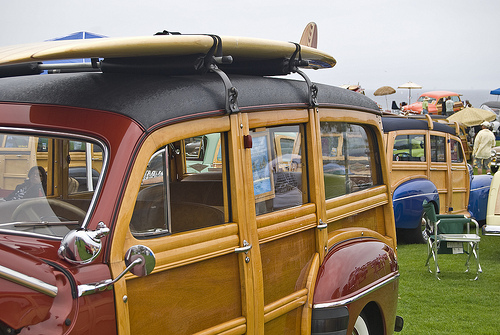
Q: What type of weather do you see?
A: It is overcast.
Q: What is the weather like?
A: It is overcast.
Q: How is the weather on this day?
A: It is overcast.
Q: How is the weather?
A: It is overcast.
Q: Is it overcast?
A: Yes, it is overcast.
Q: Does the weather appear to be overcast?
A: Yes, it is overcast.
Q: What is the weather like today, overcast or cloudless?
A: It is overcast.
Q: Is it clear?
A: No, it is overcast.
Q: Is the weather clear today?
A: No, it is overcast.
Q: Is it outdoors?
A: Yes, it is outdoors.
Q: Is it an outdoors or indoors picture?
A: It is outdoors.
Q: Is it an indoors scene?
A: No, it is outdoors.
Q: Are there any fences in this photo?
A: No, there are no fences.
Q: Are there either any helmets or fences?
A: No, there are no fences or helmets.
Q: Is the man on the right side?
A: Yes, the man is on the right of the image.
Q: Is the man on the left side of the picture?
A: No, the man is on the right of the image.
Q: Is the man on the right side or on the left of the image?
A: The man is on the right of the image.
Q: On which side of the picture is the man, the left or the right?
A: The man is on the right of the image.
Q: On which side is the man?
A: The man is on the right of the image.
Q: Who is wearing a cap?
A: The man is wearing a cap.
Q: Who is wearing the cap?
A: The man is wearing a cap.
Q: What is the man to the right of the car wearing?
A: The man is wearing a cap.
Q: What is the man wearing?
A: The man is wearing a cap.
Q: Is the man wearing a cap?
A: Yes, the man is wearing a cap.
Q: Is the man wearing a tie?
A: No, the man is wearing a cap.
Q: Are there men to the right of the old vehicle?
A: Yes, there is a man to the right of the vehicle.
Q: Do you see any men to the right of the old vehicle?
A: Yes, there is a man to the right of the vehicle.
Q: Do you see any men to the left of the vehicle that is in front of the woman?
A: No, the man is to the right of the vehicle.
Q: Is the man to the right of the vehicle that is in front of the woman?
A: Yes, the man is to the right of the vehicle.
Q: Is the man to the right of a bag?
A: No, the man is to the right of the vehicle.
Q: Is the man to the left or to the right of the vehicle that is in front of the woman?
A: The man is to the right of the vehicle.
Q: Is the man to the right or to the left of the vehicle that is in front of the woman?
A: The man is to the right of the vehicle.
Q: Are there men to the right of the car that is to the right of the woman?
A: Yes, there is a man to the right of the car.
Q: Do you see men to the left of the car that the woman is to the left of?
A: No, the man is to the right of the car.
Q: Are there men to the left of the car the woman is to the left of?
A: No, the man is to the right of the car.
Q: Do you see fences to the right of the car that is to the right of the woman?
A: No, there is a man to the right of the car.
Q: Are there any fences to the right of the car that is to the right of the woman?
A: No, there is a man to the right of the car.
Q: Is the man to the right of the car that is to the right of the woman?
A: Yes, the man is to the right of the car.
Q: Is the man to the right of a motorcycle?
A: No, the man is to the right of the car.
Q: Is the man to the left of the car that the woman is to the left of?
A: No, the man is to the right of the car.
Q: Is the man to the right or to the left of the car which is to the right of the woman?
A: The man is to the right of the car.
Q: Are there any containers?
A: No, there are no containers.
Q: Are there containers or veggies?
A: No, there are no containers or veggies.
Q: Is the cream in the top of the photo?
A: Yes, the cream is in the top of the image.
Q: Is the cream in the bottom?
A: No, the cream is in the top of the image.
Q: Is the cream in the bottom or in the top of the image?
A: The cream is in the top of the image.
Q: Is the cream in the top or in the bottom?
A: The cream is in the top of the image.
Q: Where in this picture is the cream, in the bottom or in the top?
A: The cream is in the top of the image.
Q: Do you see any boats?
A: No, there are no boats.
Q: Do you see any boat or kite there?
A: No, there are no boats or kites.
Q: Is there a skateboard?
A: No, there are no skateboards.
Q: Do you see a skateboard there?
A: No, there are no skateboards.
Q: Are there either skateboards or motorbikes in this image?
A: No, there are no skateboards or motorbikes.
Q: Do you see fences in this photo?
A: No, there are no fences.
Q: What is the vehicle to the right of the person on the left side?
A: The vehicle is a car.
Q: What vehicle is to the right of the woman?
A: The vehicle is a car.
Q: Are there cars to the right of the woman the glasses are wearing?
A: Yes, there is a car to the right of the woman.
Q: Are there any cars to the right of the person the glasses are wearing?
A: Yes, there is a car to the right of the woman.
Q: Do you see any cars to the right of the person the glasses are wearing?
A: Yes, there is a car to the right of the woman.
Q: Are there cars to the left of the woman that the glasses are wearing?
A: No, the car is to the right of the woman.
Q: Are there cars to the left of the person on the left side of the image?
A: No, the car is to the right of the woman.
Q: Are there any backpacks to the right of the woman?
A: No, there is a car to the right of the woman.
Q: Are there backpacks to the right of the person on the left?
A: No, there is a car to the right of the woman.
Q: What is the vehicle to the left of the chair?
A: The vehicle is a car.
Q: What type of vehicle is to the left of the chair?
A: The vehicle is a car.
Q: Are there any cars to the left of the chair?
A: Yes, there is a car to the left of the chair.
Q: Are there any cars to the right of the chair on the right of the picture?
A: No, the car is to the left of the chair.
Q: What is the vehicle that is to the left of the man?
A: The vehicle is a car.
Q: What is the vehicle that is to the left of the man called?
A: The vehicle is a car.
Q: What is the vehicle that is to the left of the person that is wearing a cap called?
A: The vehicle is a car.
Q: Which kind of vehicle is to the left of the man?
A: The vehicle is a car.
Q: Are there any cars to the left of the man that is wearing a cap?
A: Yes, there is a car to the left of the man.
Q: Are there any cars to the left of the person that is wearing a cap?
A: Yes, there is a car to the left of the man.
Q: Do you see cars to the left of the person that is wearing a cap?
A: Yes, there is a car to the left of the man.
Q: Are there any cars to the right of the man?
A: No, the car is to the left of the man.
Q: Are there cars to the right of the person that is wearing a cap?
A: No, the car is to the left of the man.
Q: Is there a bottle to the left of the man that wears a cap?
A: No, there is a car to the left of the man.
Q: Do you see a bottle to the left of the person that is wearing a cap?
A: No, there is a car to the left of the man.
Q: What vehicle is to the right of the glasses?
A: The vehicle is a car.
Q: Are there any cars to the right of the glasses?
A: Yes, there is a car to the right of the glasses.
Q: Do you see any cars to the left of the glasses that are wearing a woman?
A: No, the car is to the right of the glasses.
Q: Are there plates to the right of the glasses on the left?
A: No, there is a car to the right of the glasses.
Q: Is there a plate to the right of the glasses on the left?
A: No, there is a car to the right of the glasses.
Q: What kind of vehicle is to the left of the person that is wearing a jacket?
A: The vehicle is a car.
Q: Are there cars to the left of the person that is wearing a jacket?
A: Yes, there is a car to the left of the person.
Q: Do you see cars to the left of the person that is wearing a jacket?
A: Yes, there is a car to the left of the person.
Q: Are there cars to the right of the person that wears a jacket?
A: No, the car is to the left of the person.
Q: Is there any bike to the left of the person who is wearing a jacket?
A: No, there is a car to the left of the person.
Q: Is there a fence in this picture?
A: No, there are no fences.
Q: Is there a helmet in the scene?
A: No, there are no helmets.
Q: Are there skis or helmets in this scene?
A: No, there are no helmets or skis.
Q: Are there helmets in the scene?
A: No, there are no helmets.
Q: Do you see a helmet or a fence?
A: No, there are no helmets or fences.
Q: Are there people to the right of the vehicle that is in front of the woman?
A: Yes, there is a person to the right of the vehicle.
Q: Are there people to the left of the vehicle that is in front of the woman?
A: No, the person is to the right of the vehicle.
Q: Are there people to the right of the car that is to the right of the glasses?
A: Yes, there is a person to the right of the car.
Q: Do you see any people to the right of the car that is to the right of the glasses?
A: Yes, there is a person to the right of the car.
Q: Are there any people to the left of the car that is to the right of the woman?
A: No, the person is to the right of the car.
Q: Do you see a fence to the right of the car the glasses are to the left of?
A: No, there is a person to the right of the car.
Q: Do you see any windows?
A: Yes, there is a window.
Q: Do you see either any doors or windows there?
A: Yes, there is a window.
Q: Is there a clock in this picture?
A: No, there are no clocks.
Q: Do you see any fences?
A: No, there are no fences.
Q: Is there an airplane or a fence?
A: No, there are no fences or airplanes.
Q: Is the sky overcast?
A: Yes, the sky is overcast.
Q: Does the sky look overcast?
A: Yes, the sky is overcast.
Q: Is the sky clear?
A: No, the sky is overcast.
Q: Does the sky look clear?
A: No, the sky is overcast.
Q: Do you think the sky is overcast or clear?
A: The sky is overcast.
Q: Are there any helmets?
A: No, there are no helmets.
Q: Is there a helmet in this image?
A: No, there are no helmets.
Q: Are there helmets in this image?
A: No, there are no helmets.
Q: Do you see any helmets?
A: No, there are no helmets.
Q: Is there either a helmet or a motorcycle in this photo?
A: No, there are no helmets or motorcycles.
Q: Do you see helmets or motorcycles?
A: No, there are no helmets or motorcycles.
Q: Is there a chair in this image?
A: Yes, there is a chair.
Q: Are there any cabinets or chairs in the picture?
A: Yes, there is a chair.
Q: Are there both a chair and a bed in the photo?
A: No, there is a chair but no beds.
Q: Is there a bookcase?
A: No, there are no bookcases.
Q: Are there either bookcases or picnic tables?
A: No, there are no bookcases or picnic tables.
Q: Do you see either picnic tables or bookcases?
A: No, there are no bookcases or picnic tables.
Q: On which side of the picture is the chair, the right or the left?
A: The chair is on the right of the image.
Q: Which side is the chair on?
A: The chair is on the right of the image.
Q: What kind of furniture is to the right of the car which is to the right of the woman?
A: The piece of furniture is a chair.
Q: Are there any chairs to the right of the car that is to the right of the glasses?
A: Yes, there is a chair to the right of the car.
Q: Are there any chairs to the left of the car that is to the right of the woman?
A: No, the chair is to the right of the car.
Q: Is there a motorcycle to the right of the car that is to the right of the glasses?
A: No, there is a chair to the right of the car.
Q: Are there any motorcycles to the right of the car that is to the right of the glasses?
A: No, there is a chair to the right of the car.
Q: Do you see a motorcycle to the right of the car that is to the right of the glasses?
A: No, there is a chair to the right of the car.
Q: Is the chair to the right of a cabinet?
A: No, the chair is to the right of a car.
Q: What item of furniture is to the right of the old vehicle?
A: The piece of furniture is a chair.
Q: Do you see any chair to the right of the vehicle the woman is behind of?
A: Yes, there is a chair to the right of the vehicle.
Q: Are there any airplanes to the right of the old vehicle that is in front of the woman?
A: No, there is a chair to the right of the vehicle.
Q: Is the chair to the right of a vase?
A: No, the chair is to the right of the vehicle.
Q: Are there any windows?
A: Yes, there is a window.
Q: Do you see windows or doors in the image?
A: Yes, there is a window.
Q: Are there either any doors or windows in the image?
A: Yes, there is a window.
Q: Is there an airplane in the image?
A: No, there are no airplanes.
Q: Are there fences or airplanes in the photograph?
A: No, there are no airplanes or fences.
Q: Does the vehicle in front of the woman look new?
A: No, the vehicle is old.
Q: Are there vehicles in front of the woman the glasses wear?
A: Yes, there is a vehicle in front of the woman.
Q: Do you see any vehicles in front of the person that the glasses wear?
A: Yes, there is a vehicle in front of the woman.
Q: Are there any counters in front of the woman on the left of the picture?
A: No, there is a vehicle in front of the woman.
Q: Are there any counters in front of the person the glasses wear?
A: No, there is a vehicle in front of the woman.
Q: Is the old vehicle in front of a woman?
A: Yes, the vehicle is in front of a woman.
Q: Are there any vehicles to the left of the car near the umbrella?
A: Yes, there is a vehicle to the left of the car.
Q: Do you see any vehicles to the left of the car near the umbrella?
A: Yes, there is a vehicle to the left of the car.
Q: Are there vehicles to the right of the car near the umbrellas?
A: No, the vehicle is to the left of the car.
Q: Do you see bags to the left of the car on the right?
A: No, there is a vehicle to the left of the car.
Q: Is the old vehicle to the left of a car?
A: Yes, the vehicle is to the left of a car.